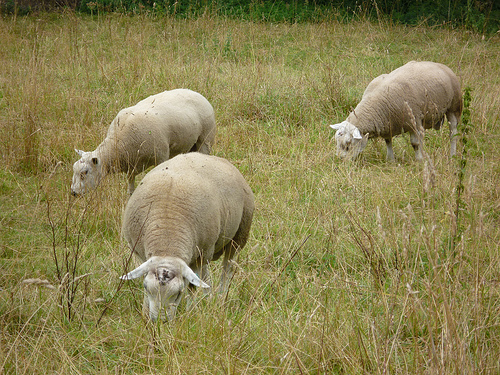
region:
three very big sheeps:
[25, 41, 497, 305]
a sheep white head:
[109, 258, 238, 329]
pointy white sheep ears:
[94, 244, 262, 301]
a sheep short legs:
[380, 92, 484, 174]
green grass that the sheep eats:
[295, 148, 493, 315]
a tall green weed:
[445, 65, 494, 258]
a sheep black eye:
[64, 157, 101, 206]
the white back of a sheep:
[141, 135, 263, 212]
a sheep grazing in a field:
[115, 158, 326, 350]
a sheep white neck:
[95, 108, 137, 194]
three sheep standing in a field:
[63, 68, 472, 314]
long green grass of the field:
[298, 205, 438, 345]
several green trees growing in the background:
[24, 0, 488, 44]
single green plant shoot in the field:
[446, 79, 473, 249]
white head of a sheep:
[113, 260, 215, 330]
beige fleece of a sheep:
[144, 158, 221, 236]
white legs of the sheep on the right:
[376, 117, 478, 173]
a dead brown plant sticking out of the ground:
[31, 186, 131, 328]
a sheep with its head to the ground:
[319, 63, 464, 172]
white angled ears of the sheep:
[115, 250, 213, 292]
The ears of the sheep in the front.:
[125, 264, 217, 291]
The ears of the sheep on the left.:
[70, 150, 105, 169]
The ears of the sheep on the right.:
[328, 118, 363, 143]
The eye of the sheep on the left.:
[71, 167, 91, 174]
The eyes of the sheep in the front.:
[144, 282, 190, 304]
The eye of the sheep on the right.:
[345, 138, 351, 143]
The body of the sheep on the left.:
[103, 95, 215, 147]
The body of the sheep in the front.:
[115, 157, 255, 248]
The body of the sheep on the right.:
[355, 57, 460, 124]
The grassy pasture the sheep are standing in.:
[20, 10, 492, 372]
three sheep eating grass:
[28, 32, 474, 334]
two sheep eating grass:
[44, 75, 271, 371]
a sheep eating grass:
[327, 33, 472, 173]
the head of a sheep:
[115, 255, 212, 331]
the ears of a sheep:
[113, 258, 212, 293]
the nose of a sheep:
[144, 310, 175, 334]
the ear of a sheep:
[181, 259, 210, 297]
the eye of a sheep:
[81, 166, 90, 178]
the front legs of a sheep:
[379, 125, 426, 163]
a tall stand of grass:
[264, 163, 496, 368]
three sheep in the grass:
[73, 26, 498, 288]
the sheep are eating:
[57, 59, 447, 322]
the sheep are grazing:
[64, 65, 467, 319]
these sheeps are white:
[43, 64, 498, 332]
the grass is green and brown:
[282, 231, 492, 348]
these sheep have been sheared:
[44, 84, 271, 345]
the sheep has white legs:
[377, 124, 459, 179]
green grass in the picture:
[214, 2, 414, 22]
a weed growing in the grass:
[454, 88, 479, 255]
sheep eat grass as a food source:
[38, 82, 290, 330]